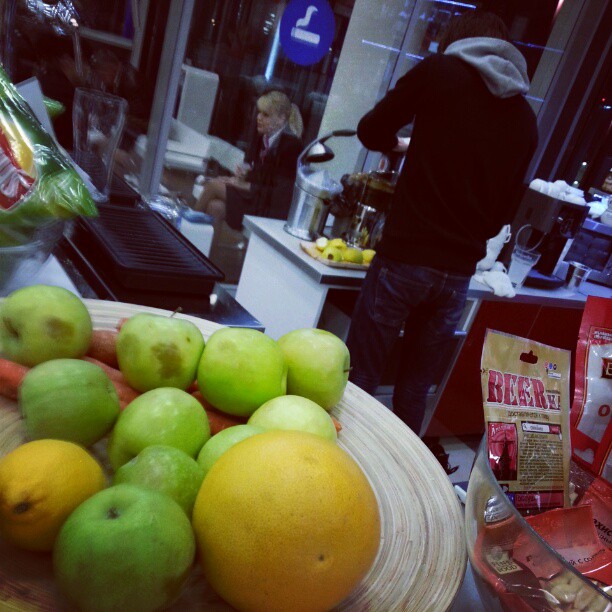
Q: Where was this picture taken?
A: In a kitchen.